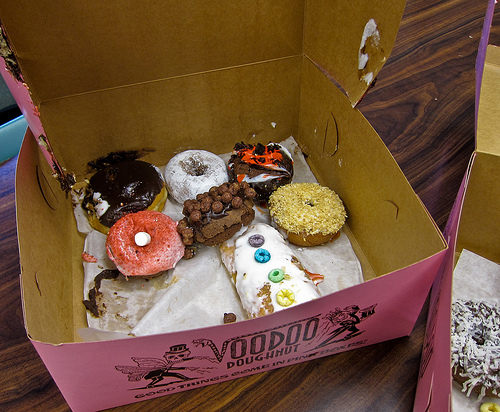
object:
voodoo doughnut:
[207, 312, 324, 369]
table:
[2, 0, 499, 409]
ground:
[363, 57, 470, 228]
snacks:
[215, 222, 323, 322]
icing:
[268, 182, 348, 234]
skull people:
[162, 343, 192, 364]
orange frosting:
[243, 152, 253, 162]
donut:
[225, 141, 296, 204]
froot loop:
[247, 233, 265, 248]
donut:
[268, 181, 348, 248]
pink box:
[411, 149, 500, 412]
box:
[410, 146, 500, 410]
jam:
[111, 181, 144, 211]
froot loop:
[267, 268, 285, 284]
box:
[0, 0, 451, 412]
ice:
[168, 172, 188, 192]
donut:
[449, 299, 500, 399]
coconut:
[481, 341, 493, 374]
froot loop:
[275, 288, 295, 307]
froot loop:
[254, 248, 272, 264]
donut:
[218, 222, 324, 320]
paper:
[84, 133, 366, 332]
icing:
[356, 18, 389, 87]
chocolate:
[100, 161, 153, 206]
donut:
[176, 181, 257, 253]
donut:
[104, 210, 185, 281]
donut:
[163, 149, 231, 205]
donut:
[81, 159, 168, 235]